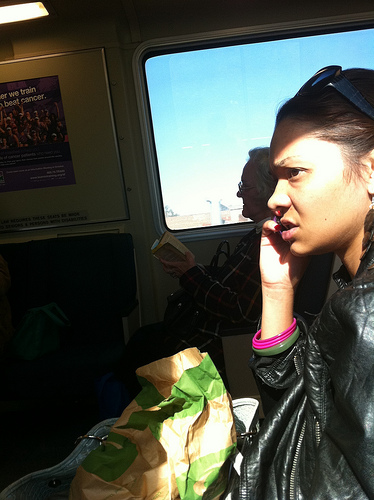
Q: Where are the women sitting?
A: On train.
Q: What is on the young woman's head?
A: Glasses.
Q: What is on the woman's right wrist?
A: Bracelets.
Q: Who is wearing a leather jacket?
A: Young woman.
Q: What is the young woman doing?
A: Talking on phone.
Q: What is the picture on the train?
A: Advertisement.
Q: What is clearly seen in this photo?
A: Woman with pink bangles.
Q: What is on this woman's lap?
A: Tan and green bag.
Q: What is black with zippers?
A: Jacket.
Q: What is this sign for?
A: For beating cancer.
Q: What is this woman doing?
A: Talking on a cellphone.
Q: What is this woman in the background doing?
A: Reading a book.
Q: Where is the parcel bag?
A: Woman is holding it on her lap.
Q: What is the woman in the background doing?
A: Reading.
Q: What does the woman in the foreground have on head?
A: Sunglasses.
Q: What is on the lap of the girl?
A: Bag.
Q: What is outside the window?
A: Sky.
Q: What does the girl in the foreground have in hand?
A: Phone.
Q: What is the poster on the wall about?
A: Cancer.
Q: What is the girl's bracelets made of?
A: Plastic.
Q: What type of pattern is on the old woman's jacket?
A: Plaid.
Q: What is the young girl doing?
A: Talking on phone.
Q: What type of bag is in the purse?
A: Paper.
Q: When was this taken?
A: During the day.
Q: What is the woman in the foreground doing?
A: Talking on a phone.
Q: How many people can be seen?
A: Two.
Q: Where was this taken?
A: On a train.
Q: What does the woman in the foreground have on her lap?
A: A bag.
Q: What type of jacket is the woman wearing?
A: A leather jacket.